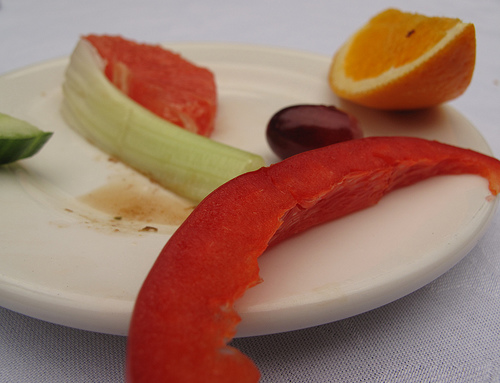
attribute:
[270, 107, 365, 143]
grape — small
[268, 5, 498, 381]
cloth — white 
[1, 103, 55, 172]
cucumber — green, sliced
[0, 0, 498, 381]
cloth — white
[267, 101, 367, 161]
grape — purple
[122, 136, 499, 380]
grapefruit slice — sliced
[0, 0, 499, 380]
gray table — gray 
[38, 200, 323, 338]
plate — round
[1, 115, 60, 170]
watermelon — piece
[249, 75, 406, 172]
grape — oval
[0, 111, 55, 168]
cucumber — green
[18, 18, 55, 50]
wall — white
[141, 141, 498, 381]
food piece — red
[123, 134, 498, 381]
food — long, red, sliced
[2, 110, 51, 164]
cucumber — green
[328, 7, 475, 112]
orange — sliced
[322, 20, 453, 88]
orange — sliced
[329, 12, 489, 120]
orange — cut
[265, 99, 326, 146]
grape — purple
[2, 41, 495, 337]
plate — white